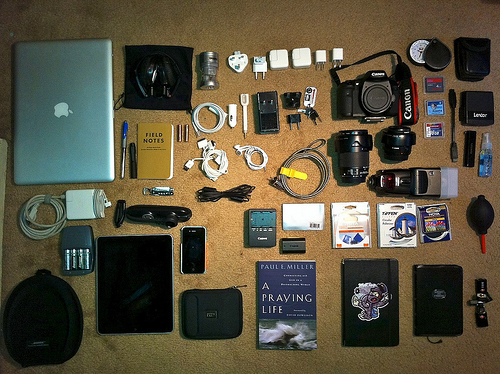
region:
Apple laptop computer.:
[11, 40, 115, 182]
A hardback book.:
[257, 261, 319, 349]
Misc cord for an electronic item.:
[195, 185, 258, 202]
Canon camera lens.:
[332, 128, 370, 186]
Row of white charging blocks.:
[267, 48, 345, 68]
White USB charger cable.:
[184, 138, 231, 180]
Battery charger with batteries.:
[59, 226, 95, 276]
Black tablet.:
[94, 235, 174, 335]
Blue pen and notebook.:
[117, 118, 174, 176]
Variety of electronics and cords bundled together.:
[10, 188, 249, 370]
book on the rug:
[253, 253, 318, 361]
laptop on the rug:
[7, 38, 120, 184]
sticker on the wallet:
[347, 268, 395, 332]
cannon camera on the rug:
[335, 65, 416, 122]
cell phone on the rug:
[179, 224, 209, 276]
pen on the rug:
[116, 115, 128, 185]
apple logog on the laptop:
[46, 96, 78, 127]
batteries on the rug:
[62, 248, 89, 273]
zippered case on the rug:
[180, 278, 250, 347]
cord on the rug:
[265, 135, 328, 198]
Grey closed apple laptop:
[8, 37, 115, 186]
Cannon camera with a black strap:
[322, 47, 424, 129]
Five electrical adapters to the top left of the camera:
[225, 44, 347, 81]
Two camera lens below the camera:
[329, 122, 417, 191]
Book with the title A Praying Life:
[252, 257, 320, 355]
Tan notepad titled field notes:
[134, 119, 177, 184]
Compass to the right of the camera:
[406, 35, 453, 74]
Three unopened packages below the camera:
[328, 199, 455, 251]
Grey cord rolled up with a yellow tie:
[265, 137, 331, 201]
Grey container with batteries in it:
[55, 222, 97, 279]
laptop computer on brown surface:
[7, 28, 121, 189]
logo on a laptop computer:
[48, 95, 78, 126]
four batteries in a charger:
[57, 241, 92, 272]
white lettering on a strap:
[401, 85, 416, 122]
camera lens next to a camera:
[329, 124, 376, 188]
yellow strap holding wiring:
[275, 163, 311, 184]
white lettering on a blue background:
[257, 290, 315, 304]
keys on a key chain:
[302, 103, 325, 128]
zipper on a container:
[227, 281, 250, 293]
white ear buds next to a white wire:
[229, 140, 274, 175]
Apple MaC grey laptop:
[11, 36, 116, 185]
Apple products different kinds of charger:
[265, 45, 345, 68]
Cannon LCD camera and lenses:
[336, 62, 416, 187]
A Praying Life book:
[254, 256, 319, 353]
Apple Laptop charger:
[16, 185, 111, 237]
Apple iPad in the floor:
[96, 232, 176, 340]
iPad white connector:
[182, 133, 237, 178]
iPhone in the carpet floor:
[174, 225, 213, 280]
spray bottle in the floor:
[480, 130, 492, 179]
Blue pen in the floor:
[116, 119, 133, 179]